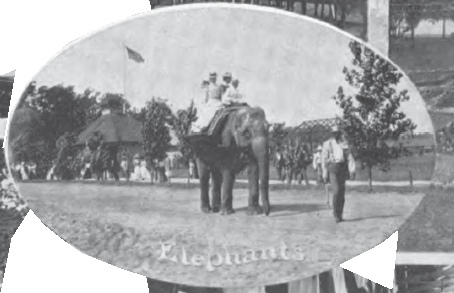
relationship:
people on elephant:
[194, 73, 253, 103] [182, 116, 267, 206]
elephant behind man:
[182, 116, 267, 206] [310, 128, 358, 212]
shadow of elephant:
[274, 202, 329, 218] [182, 116, 267, 206]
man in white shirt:
[310, 128, 358, 212] [310, 143, 356, 163]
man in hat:
[310, 128, 358, 212] [329, 123, 346, 137]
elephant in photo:
[182, 116, 267, 206] [22, 39, 448, 274]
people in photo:
[194, 73, 253, 103] [22, 39, 448, 274]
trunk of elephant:
[252, 133, 271, 216] [182, 116, 267, 206]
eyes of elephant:
[241, 125, 282, 140] [182, 116, 267, 206]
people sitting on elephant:
[194, 73, 253, 103] [182, 116, 267, 206]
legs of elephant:
[215, 167, 257, 215] [182, 116, 267, 206]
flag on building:
[116, 45, 154, 67] [67, 108, 173, 180]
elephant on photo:
[182, 116, 267, 206] [22, 39, 448, 274]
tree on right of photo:
[354, 44, 406, 193] [398, 68, 441, 205]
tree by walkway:
[354, 44, 406, 193] [135, 191, 194, 218]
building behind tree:
[67, 108, 173, 180] [354, 44, 406, 193]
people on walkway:
[194, 73, 253, 103] [135, 191, 194, 218]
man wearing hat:
[310, 128, 358, 212] [329, 123, 346, 137]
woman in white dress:
[230, 79, 244, 102] [228, 94, 237, 102]